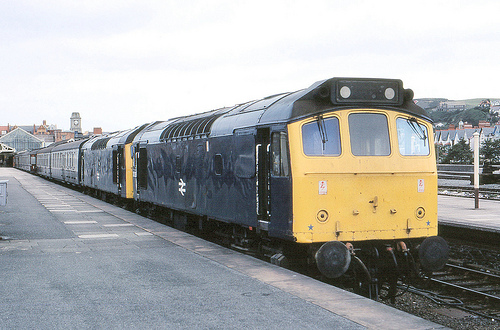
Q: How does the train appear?
A: Visible.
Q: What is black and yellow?
A: Train.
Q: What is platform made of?
A: Cement.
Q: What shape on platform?
A: Rectangle.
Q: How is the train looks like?
A: Old.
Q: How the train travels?
A: Tracks.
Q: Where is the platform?
A: Side to train.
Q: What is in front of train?
A: Lights.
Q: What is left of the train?
A: Concrete platform.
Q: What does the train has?
A: Multiple black cars.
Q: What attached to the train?
A: Cars.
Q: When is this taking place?
A: Daytime.